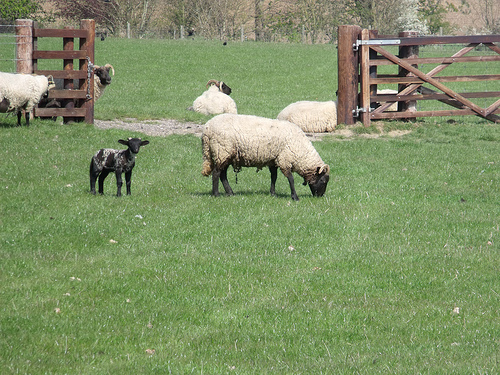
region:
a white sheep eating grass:
[204, 104, 334, 207]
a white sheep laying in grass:
[189, 68, 249, 126]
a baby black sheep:
[73, 129, 143, 209]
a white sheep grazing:
[1, 72, 108, 134]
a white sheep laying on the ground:
[279, 90, 347, 135]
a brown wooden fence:
[324, 10, 499, 127]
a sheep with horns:
[90, 56, 120, 94]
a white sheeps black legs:
[212, 156, 239, 200]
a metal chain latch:
[81, 52, 98, 102]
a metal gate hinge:
[349, 32, 404, 54]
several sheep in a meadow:
[1, 45, 351, 208]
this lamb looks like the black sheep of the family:
[80, 133, 155, 202]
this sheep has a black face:
[306, 160, 336, 200]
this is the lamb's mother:
[196, 108, 341, 206]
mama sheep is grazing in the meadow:
[196, 108, 339, 205]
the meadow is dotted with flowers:
[49, 266, 86, 325]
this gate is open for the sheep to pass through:
[48, 10, 388, 136]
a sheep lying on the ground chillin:
[185, 72, 247, 124]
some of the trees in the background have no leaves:
[88, 1, 466, 39]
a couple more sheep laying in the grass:
[269, 81, 416, 141]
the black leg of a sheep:
[85, 173, 100, 196]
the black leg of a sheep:
[99, 167, 108, 194]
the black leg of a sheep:
[115, 168, 123, 195]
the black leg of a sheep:
[124, 166, 133, 195]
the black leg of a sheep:
[209, 157, 221, 198]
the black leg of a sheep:
[218, 157, 232, 194]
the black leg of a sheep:
[267, 159, 278, 196]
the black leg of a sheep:
[282, 163, 299, 200]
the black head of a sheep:
[306, 164, 332, 197]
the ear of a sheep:
[320, 163, 330, 176]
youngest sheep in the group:
[79, 129, 153, 199]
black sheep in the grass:
[82, 134, 152, 199]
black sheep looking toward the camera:
[88, 132, 153, 196]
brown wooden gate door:
[356, 25, 496, 137]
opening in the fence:
[89, 18, 348, 134]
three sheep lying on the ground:
[187, 73, 422, 138]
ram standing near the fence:
[33, 55, 118, 128]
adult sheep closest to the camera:
[196, 105, 337, 206]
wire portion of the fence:
[0, 21, 27, 96]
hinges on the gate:
[352, 35, 364, 121]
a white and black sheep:
[201, 112, 331, 200]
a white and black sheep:
[274, 98, 337, 135]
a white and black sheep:
[191, 79, 238, 116]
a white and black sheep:
[90, 61, 115, 105]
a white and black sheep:
[1, 71, 53, 126]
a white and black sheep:
[376, 87, 396, 112]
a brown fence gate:
[361, 28, 498, 120]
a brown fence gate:
[29, 20, 94, 120]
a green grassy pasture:
[4, 35, 496, 373]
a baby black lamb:
[85, 136, 149, 193]